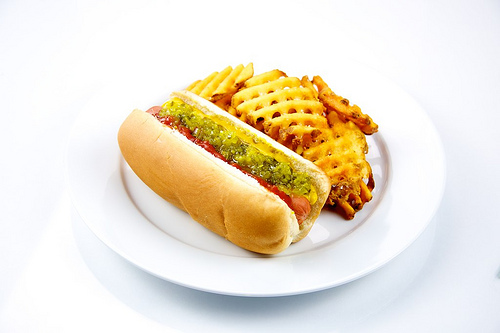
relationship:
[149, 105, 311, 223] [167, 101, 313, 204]
hot dog with sauces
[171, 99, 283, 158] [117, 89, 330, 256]
mustard on a hot dog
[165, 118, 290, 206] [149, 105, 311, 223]
ketchup on hot dog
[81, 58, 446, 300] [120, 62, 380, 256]
plate of food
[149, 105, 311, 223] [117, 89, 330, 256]
hot dog in a hot dog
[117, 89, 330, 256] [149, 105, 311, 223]
hot dog enclosing hot dog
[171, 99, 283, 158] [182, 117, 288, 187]
mustard and relish toppings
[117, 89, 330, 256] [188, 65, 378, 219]
hot dog next to fries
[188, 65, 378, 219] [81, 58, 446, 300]
fries on plate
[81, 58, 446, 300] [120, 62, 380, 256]
plate under food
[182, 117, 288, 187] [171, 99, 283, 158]
relish toppings between ketchup and mustard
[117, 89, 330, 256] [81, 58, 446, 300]
hot dog on plate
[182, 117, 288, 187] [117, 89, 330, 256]
relish toppings on hot dog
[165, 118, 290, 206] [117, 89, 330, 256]
ketchup on hot dog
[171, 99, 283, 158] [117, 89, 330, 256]
mustard on hot dog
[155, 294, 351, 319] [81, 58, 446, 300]
shadow from plate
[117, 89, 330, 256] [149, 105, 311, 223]
hot dog for hot dog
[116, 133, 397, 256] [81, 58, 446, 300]
ridge on plate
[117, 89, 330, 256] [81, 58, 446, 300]
hot dog on a white plate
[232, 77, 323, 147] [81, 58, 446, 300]
waffle fry on plate